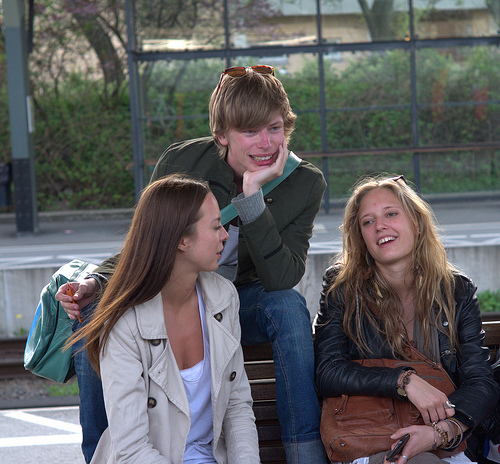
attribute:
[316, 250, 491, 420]
jacket — black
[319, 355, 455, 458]
bag — large, brown, leather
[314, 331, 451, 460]
purse — brown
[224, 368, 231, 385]
button — large, brown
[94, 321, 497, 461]
bench — wooden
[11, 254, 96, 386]
satchel — green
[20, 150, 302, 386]
bag — green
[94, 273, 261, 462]
pea-coat — white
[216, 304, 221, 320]
button — dark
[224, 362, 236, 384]
button — dark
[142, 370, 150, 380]
button — dark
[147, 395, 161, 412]
button — dark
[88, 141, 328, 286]
jacket — green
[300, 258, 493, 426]
leather jacket — black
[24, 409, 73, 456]
lines — white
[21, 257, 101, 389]
bag — blue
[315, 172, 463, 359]
hair — curly, blond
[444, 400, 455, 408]
ring — large, dark stoned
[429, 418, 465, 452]
bracelets — worn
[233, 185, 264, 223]
cuff — grey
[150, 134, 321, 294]
sweater — GREEN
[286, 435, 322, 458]
jeans — rolled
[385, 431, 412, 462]
phone — small, black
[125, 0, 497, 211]
fence — large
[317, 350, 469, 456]
purse — large, brown